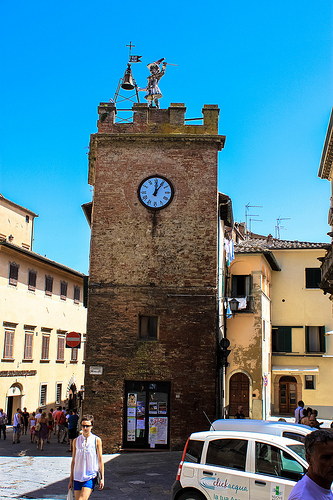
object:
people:
[12, 408, 22, 445]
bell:
[120, 63, 135, 91]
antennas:
[244, 201, 291, 241]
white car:
[209, 419, 319, 446]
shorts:
[13, 426, 19, 435]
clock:
[137, 174, 175, 211]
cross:
[126, 41, 136, 51]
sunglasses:
[81, 424, 94, 428]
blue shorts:
[72, 470, 95, 492]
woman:
[35, 411, 50, 451]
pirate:
[136, 57, 178, 108]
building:
[77, 102, 234, 456]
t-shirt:
[287, 473, 332, 500]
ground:
[105, 454, 171, 500]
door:
[147, 381, 170, 450]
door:
[123, 380, 147, 448]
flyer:
[127, 393, 137, 407]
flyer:
[127, 407, 136, 417]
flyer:
[127, 417, 136, 431]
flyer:
[127, 432, 136, 442]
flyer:
[158, 402, 167, 415]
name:
[198, 476, 248, 495]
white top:
[73, 432, 97, 483]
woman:
[67, 413, 105, 500]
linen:
[227, 296, 247, 311]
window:
[231, 273, 252, 312]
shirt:
[73, 432, 98, 483]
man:
[287, 429, 333, 500]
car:
[170, 410, 309, 500]